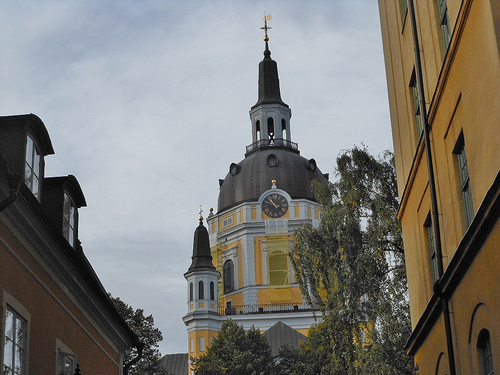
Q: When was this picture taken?
A: During the day.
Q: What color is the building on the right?
A: Yellow.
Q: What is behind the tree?
A: A cathedral.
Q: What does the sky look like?
A: Cloudy.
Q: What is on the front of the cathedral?
A: A clock.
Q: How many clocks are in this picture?
A: One.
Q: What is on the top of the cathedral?
A: A cross.